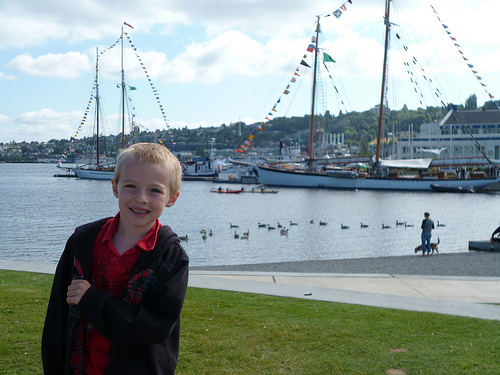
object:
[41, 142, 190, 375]
boy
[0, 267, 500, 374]
grass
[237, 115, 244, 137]
tower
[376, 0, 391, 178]
mast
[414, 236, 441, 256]
dog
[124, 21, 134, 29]
flag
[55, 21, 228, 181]
boat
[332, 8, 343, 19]
flags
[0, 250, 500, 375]
ground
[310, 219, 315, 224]
ducks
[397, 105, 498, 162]
building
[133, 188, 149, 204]
nose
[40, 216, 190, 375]
coat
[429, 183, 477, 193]
boat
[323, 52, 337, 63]
flag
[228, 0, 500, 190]
boat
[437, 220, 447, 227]
birds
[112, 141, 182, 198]
hair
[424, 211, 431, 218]
hair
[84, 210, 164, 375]
shirt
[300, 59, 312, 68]
banners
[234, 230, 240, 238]
bird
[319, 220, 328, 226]
bird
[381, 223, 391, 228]
bird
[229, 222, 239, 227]
bird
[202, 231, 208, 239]
bird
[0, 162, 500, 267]
water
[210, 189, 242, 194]
boat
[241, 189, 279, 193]
boat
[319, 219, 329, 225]
bird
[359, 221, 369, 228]
bird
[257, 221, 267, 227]
bird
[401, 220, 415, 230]
bird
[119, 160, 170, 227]
face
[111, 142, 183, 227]
head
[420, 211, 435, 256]
man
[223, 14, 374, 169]
boat